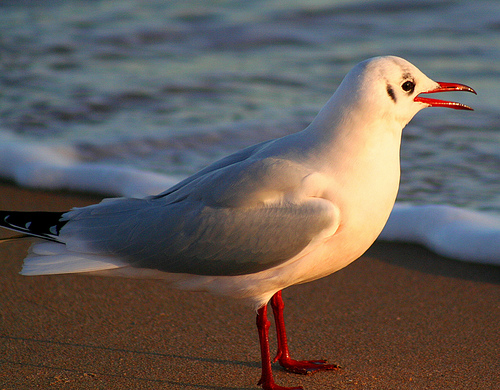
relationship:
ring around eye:
[396, 77, 417, 99] [402, 81, 413, 92]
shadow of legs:
[3, 335, 258, 389] [255, 290, 342, 388]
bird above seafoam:
[1, 53, 479, 388] [391, 204, 500, 266]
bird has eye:
[1, 56, 479, 389] [402, 81, 413, 92]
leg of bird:
[273, 290, 290, 356] [1, 56, 479, 389]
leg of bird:
[258, 302, 273, 375] [1, 56, 479, 389]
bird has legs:
[1, 56, 479, 389] [255, 290, 342, 388]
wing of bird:
[61, 197, 342, 277] [1, 56, 479, 389]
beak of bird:
[413, 81, 477, 114] [1, 56, 479, 389]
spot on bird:
[386, 85, 397, 102] [1, 56, 479, 389]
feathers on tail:
[2, 208, 65, 244] [20, 243, 121, 277]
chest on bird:
[344, 178, 400, 247] [1, 56, 479, 389]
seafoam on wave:
[391, 204, 500, 266] [400, 166, 498, 208]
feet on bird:
[265, 353, 342, 388] [1, 56, 479, 389]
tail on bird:
[20, 243, 121, 277] [1, 56, 479, 389]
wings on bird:
[64, 154, 327, 277] [1, 56, 479, 389]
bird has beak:
[1, 56, 479, 389] [413, 81, 477, 114]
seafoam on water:
[391, 204, 500, 266] [3, 2, 303, 128]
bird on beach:
[1, 56, 479, 389] [3, 245, 500, 389]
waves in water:
[1, 93, 306, 136] [3, 2, 303, 128]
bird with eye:
[1, 56, 479, 389] [402, 81, 413, 92]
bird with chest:
[1, 56, 479, 389] [344, 178, 400, 247]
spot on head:
[386, 85, 397, 102] [345, 55, 427, 135]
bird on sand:
[1, 53, 479, 388] [306, 318, 391, 356]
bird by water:
[1, 53, 479, 388] [3, 2, 303, 128]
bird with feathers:
[1, 53, 479, 388] [2, 208, 65, 244]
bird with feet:
[1, 53, 479, 388] [265, 353, 342, 388]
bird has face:
[1, 53, 479, 388] [404, 63, 428, 118]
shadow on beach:
[3, 335, 258, 389] [3, 245, 500, 389]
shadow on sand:
[3, 335, 258, 389] [306, 318, 391, 356]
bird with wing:
[1, 53, 479, 388] [61, 197, 342, 277]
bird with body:
[1, 56, 479, 389] [154, 133, 401, 302]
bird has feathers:
[1, 56, 479, 389] [2, 208, 65, 244]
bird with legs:
[1, 56, 479, 389] [255, 290, 342, 388]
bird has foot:
[1, 53, 479, 388] [276, 353, 343, 376]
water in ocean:
[3, 2, 303, 128] [2, 0, 500, 229]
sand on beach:
[306, 318, 391, 356] [3, 245, 500, 389]